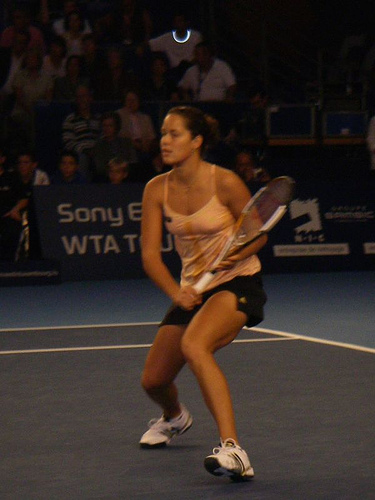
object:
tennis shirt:
[162, 161, 262, 294]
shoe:
[138, 401, 193, 448]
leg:
[139, 285, 207, 447]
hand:
[176, 285, 203, 310]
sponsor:
[273, 195, 351, 260]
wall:
[341, 167, 374, 265]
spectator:
[105, 155, 132, 184]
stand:
[29, 114, 138, 289]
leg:
[181, 288, 255, 483]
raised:
[206, 455, 240, 500]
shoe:
[203, 435, 256, 481]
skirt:
[188, 290, 249, 329]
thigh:
[181, 284, 248, 347]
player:
[139, 104, 270, 481]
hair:
[168, 104, 228, 152]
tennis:
[190, 173, 295, 293]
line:
[23, 340, 153, 355]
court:
[0, 272, 374, 499]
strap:
[208, 162, 219, 196]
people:
[61, 83, 109, 158]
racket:
[192, 174, 296, 294]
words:
[61, 232, 91, 257]